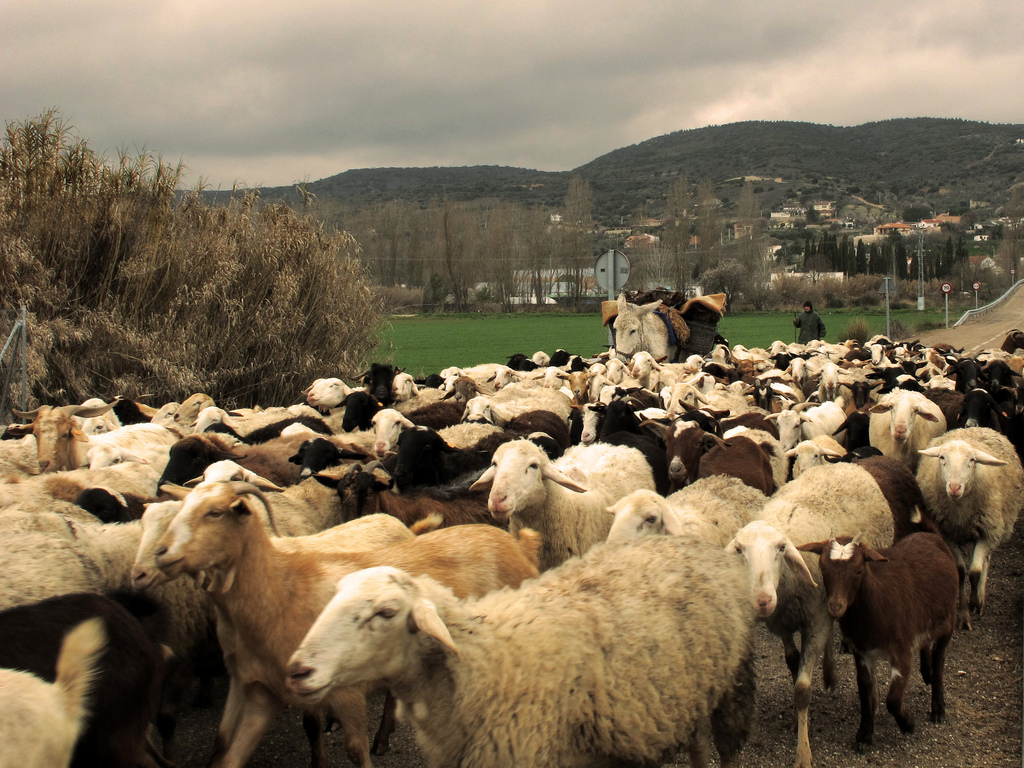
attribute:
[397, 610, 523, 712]
ear — white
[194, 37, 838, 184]
sky — cloudy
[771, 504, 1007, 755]
sheep — small, brown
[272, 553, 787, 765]
sheep — tan, furry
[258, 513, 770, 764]
sheep — shaggy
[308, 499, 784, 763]
sheep — white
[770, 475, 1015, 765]
sheep — small, brown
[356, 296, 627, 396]
field — grassy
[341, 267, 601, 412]
field — green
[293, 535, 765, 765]
sheep — white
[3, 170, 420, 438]
trees — tall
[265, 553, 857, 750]
sheep — white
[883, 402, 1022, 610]
sheep — white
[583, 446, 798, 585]
sheep — white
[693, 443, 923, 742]
sheep — white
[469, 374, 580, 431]
sheep — white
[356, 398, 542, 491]
sheep — white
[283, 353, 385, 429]
sheep — white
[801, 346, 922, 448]
sheep — white